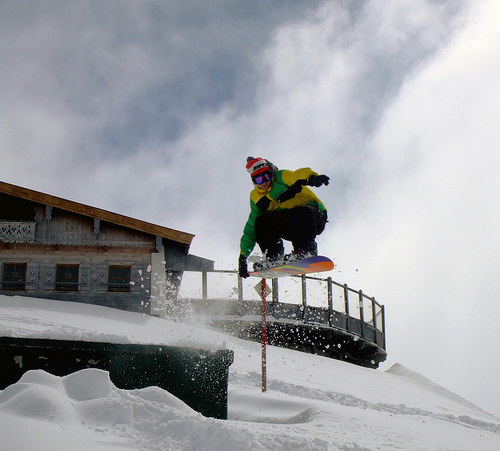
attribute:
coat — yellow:
[243, 175, 350, 264]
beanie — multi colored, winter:
[241, 152, 268, 173]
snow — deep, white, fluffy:
[329, 371, 412, 412]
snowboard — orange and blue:
[247, 253, 334, 279]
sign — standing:
[238, 275, 282, 417]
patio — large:
[168, 252, 393, 364]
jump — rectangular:
[2, 330, 235, 430]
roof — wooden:
[1, 176, 195, 249]